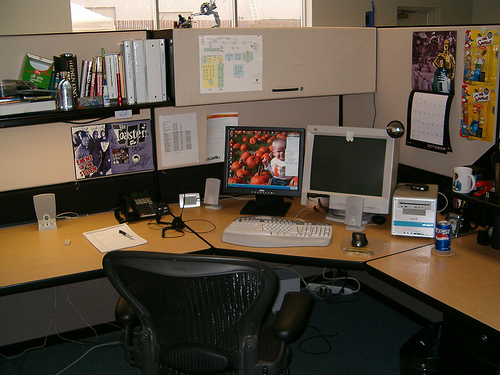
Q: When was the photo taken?
A: Daytime.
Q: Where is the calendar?
A: Wall.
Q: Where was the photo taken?
A: At an office building.